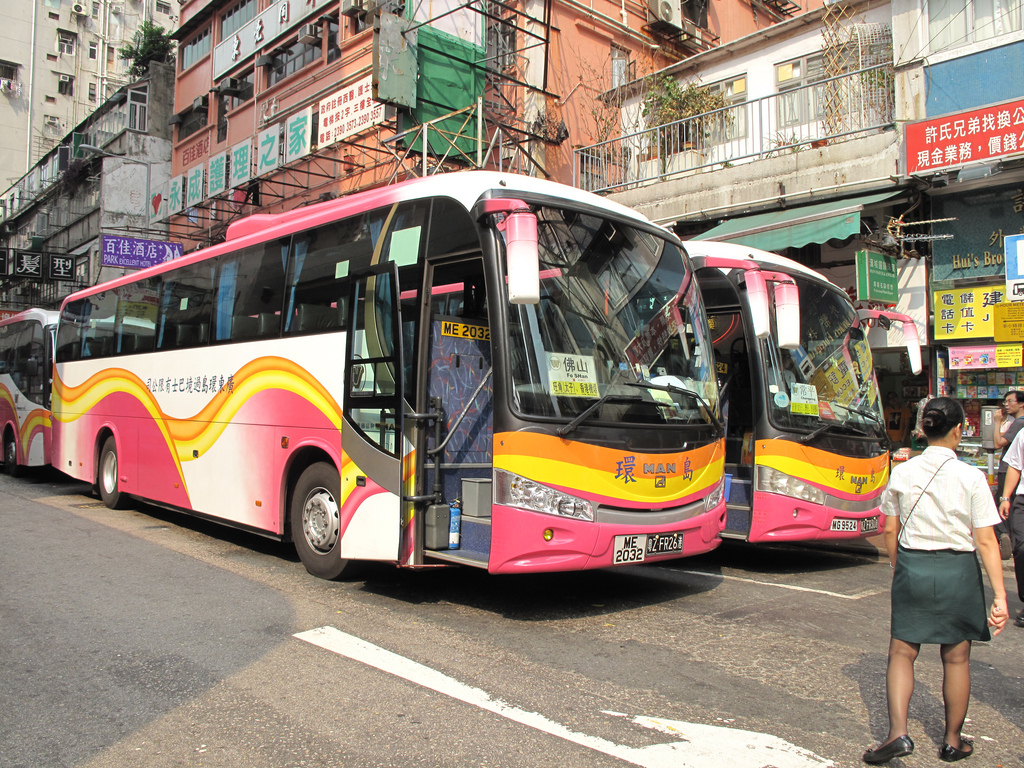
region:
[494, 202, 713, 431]
window attached to bus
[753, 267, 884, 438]
window attached to bus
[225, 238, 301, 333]
window attached to bus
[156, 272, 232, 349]
window attached to bus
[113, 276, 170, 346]
window attached to bus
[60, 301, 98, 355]
window attached to bus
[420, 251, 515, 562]
door way to the bus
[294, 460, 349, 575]
tire attached to bus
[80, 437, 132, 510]
tire attached to bus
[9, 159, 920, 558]
Pink,white,yellow,and orange buses.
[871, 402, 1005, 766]
Person wearing skirt and blouse.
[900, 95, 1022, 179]
Red and white sign on building.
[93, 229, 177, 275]
Purple and white sign over bus.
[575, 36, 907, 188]
Silver railing on balcony.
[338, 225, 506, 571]
Open door on bus.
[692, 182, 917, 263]
Green awning on building.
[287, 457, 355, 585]
Black tire and silver hub cap.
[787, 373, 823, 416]
Yellow and white sticker on windshield.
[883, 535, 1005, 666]
Woman wearing a skirt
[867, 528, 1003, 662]
Woman is wearing a skirt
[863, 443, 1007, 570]
Woman is wearing a shirt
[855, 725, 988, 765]
Woman wearing shoes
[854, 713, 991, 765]
Woman is wearing black shoes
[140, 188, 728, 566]
a bus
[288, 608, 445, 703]
white line in the street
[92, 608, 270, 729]
the street is grey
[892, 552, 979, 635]
a green skirt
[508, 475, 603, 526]
the headlight is clear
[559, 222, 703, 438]
a windshield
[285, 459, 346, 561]
front tire on the bus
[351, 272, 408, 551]
the door of the bus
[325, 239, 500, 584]
the door of the bus is open